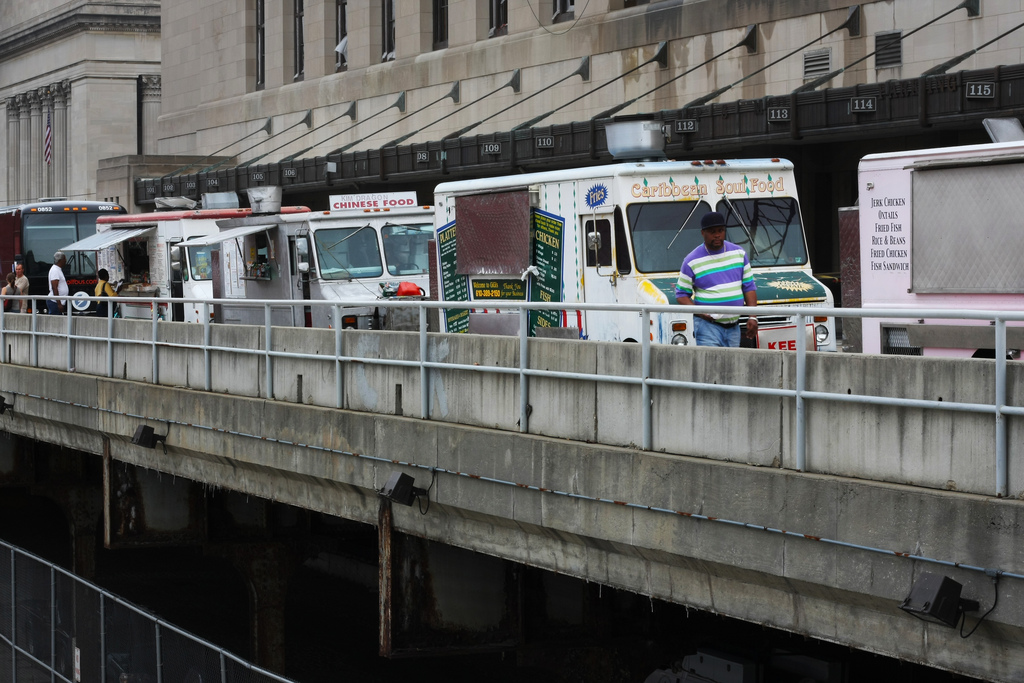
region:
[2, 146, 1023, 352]
food trucks lined up along road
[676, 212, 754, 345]
man wearing a striped shirt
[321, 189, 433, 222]
chinese food truck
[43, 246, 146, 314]
people waiting in line at food truck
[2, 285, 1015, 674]
overpass where food trucks are sitting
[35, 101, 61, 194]
american flag in background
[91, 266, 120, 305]
woman wearing a yellow shirt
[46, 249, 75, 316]
man wearing a white tshirt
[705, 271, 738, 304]
the mans shirt is stripped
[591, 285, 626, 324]
the truck is white in color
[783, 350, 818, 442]
the pipe is gray in color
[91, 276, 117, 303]
the persons shirt is yellow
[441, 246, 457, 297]
the sign on the truck is green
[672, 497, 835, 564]
the pipe has rust on it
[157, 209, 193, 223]
the roof of the truck is red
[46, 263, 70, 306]
the mans shirt is white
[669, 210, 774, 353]
man walking on overpass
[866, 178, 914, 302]
black words printed on truck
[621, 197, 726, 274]
windshield on the truck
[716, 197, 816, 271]
windshield on the truck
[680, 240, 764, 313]
striped shirt on the man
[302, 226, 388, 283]
windshield on the truck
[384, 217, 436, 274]
windshield on the truck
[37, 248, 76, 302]
man standing near truck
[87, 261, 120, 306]
person in yellow near truck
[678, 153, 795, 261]
a man wearing a hat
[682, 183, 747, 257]
the face of a man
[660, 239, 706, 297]
the shoulder of a man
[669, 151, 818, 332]
a man wearing a shirt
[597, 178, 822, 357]
a man near a truck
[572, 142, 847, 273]
the windshield of a truck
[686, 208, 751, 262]
the eyes of a man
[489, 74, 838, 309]
a truck near a building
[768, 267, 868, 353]
the headlight on a truck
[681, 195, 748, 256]
a man wearing a hat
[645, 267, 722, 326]
the arm of a man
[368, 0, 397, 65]
glass window in the building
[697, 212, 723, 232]
a man wearing a black hat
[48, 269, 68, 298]
a man wearing a white shirt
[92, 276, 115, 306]
a woman wearing a yellow shirt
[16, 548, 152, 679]
a chain link fence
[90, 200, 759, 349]
three vans parked in a row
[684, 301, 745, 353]
a man wearing blue jeans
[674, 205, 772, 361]
A man standing on edge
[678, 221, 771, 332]
A man in a striped shirt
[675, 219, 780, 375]
A man standing by bridge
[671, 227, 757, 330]
A man that is walking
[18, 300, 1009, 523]
Long white metal railing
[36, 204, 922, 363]
Many vehicles lined in a row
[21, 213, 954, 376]
Lots of trucks parked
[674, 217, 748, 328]
Striped shit worn by a man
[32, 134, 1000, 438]
A line of food trucks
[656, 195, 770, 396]
A man in a striped shirt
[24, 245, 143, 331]
People standing at the food truck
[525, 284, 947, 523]
Metal rail on the bridge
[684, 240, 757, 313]
striped shirt worn by human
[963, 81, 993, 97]
A number on the building.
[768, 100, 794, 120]
A number on the building.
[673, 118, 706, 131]
A number on the building.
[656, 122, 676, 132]
A number on the building.